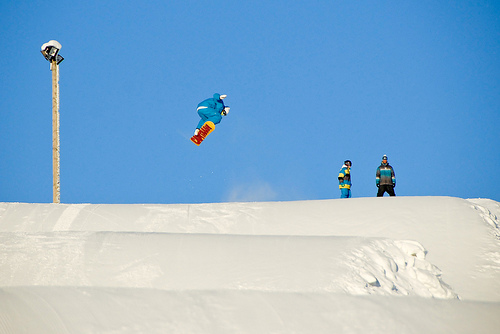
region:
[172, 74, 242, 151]
Person is in the air.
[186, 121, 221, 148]
The snowboard is yellow and red.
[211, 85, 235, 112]
The gloves are white.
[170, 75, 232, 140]
The person is wearing blue.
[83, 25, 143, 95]
The sky is blue.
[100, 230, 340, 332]
The ground is white.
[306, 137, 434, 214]
Two people standing on the ground.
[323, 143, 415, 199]
The two people are dressed the same.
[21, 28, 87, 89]
Light on top of a pole.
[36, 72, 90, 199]
The pole is tan.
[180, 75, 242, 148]
airborne snow boarder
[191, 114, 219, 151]
snow boarder on yellow and red board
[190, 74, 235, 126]
snow boarder wearing blue and white outfit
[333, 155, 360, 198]
person wearing blue and yellow outfit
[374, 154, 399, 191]
person wearing black, blue and yellow outfit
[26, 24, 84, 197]
light post in snow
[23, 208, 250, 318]
soft white snow on mountain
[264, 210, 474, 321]
white snow on mountain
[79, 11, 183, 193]
clear blue cloudless sky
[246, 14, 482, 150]
clear blue cloudless sky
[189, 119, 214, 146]
yellow and red snowboard in air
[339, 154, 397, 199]
two people standing on snow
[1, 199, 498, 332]
snow-covered hill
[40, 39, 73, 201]
lamp post on hill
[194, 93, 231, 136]
person in blue snow gear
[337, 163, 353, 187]
blue and yellow snow jacket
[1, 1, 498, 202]
a clear, blue sky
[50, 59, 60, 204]
wooden pole under lights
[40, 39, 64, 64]
lights with snow on top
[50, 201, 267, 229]
tracks in the snow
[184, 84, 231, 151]
the snowboarder is in the air!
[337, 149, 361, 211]
the person has on a blue snowsuit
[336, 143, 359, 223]
the snowsuit also has yellow on it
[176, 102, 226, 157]
the snowboard is yellow with red letters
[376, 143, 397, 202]
this person is wearing a multi colored jacket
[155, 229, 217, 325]
the snow is very bright white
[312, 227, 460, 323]
the snow appears to be drifted deep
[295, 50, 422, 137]
the sky is a brilliant blue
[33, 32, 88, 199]
a light stands on top the mountain for night skiing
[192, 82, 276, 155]
the snowboarder is wearing a blue snowsuit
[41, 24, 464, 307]
There is snow on the background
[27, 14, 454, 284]
The sky is blue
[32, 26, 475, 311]
There are three people in the photo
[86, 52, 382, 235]
There is a person snowboarding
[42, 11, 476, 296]
There are no clouds in the sky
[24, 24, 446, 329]
The snowboarder is going down the ski slope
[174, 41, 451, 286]
There are two people on top of the ski slope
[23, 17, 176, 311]
There is a pole in the snow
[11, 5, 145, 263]
The pole has a light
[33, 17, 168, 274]
The light has snow on top